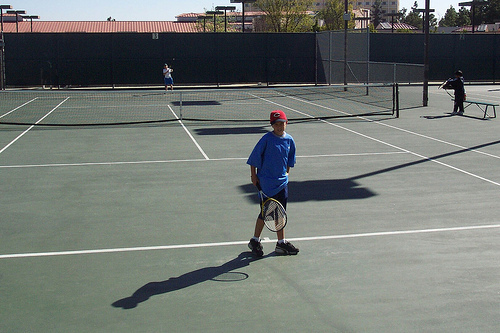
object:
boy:
[244, 109, 300, 257]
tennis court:
[0, 84, 500, 333]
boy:
[445, 69, 467, 116]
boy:
[162, 63, 175, 95]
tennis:
[171, 57, 177, 61]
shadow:
[169, 100, 223, 106]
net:
[0, 82, 396, 126]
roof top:
[0, 22, 211, 32]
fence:
[316, 28, 429, 106]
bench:
[451, 98, 500, 121]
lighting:
[7, 6, 26, 20]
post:
[15, 14, 19, 34]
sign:
[343, 13, 351, 21]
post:
[342, 0, 349, 91]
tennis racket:
[250, 175, 288, 233]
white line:
[167, 105, 210, 160]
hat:
[268, 110, 288, 124]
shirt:
[246, 131, 298, 198]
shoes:
[247, 238, 265, 257]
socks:
[252, 237, 261, 243]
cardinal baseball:
[274, 113, 281, 118]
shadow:
[109, 251, 294, 311]